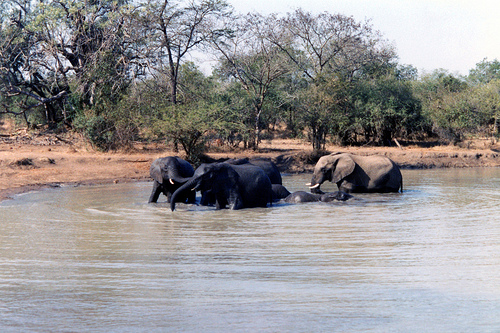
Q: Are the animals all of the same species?
A: Yes, all the animals are elephants.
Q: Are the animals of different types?
A: No, all the animals are elephants.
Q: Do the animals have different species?
A: No, all the animals are elephants.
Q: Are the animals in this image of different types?
A: No, all the animals are elephants.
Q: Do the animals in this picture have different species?
A: No, all the animals are elephants.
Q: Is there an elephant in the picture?
A: Yes, there is an elephant.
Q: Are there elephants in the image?
A: Yes, there is an elephant.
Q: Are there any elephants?
A: Yes, there is an elephant.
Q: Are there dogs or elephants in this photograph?
A: Yes, there is an elephant.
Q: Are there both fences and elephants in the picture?
A: No, there is an elephant but no fences.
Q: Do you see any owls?
A: No, there are no owls.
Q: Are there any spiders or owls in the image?
A: No, there are no owls or spiders.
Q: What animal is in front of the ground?
A: The animal is an elephant.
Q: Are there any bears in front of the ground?
A: No, there is an elephant in front of the ground.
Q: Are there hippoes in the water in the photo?
A: No, there is an elephant in the water.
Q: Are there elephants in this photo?
A: Yes, there is an elephant.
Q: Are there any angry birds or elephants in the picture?
A: Yes, there is an elephant.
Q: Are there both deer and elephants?
A: No, there is an elephant but no deer.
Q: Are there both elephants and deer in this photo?
A: No, there is an elephant but no deer.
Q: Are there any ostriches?
A: No, there are no ostriches.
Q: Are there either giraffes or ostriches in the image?
A: No, there are no ostriches or giraffes.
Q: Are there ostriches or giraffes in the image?
A: No, there are no ostriches or giraffes.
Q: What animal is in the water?
A: The animal is an elephant.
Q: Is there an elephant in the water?
A: Yes, there is an elephant in the water.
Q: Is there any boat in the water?
A: No, there is an elephant in the water.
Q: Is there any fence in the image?
A: No, there are no fences.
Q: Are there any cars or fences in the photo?
A: No, there are no fences or cars.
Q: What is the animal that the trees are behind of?
A: The animal is an elephant.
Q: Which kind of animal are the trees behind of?
A: The trees are behind the elephant.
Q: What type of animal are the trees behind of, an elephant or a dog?
A: The trees are behind an elephant.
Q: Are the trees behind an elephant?
A: Yes, the trees are behind an elephant.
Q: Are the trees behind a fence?
A: No, the trees are behind an elephant.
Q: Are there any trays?
A: No, there are no trays.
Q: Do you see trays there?
A: No, there are no trays.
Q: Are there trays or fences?
A: No, there are no trays or fences.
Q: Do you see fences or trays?
A: No, there are no trays or fences.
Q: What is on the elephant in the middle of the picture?
A: The trunk is on the elephant.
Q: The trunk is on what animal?
A: The trunk is on the elephant.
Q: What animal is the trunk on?
A: The trunk is on the elephant.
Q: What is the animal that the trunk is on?
A: The animal is an elephant.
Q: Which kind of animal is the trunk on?
A: The trunk is on the elephant.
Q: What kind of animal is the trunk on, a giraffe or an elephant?
A: The trunk is on an elephant.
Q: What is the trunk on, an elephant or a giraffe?
A: The trunk is on an elephant.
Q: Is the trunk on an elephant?
A: Yes, the trunk is on an elephant.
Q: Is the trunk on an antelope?
A: No, the trunk is on an elephant.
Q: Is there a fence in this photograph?
A: No, there are no fences.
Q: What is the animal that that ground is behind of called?
A: The animal is an elephant.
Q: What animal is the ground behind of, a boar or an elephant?
A: The ground is behind an elephant.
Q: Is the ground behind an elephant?
A: Yes, the ground is behind an elephant.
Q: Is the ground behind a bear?
A: No, the ground is behind an elephant.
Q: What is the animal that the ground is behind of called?
A: The animal is an elephant.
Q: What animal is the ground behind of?
A: The ground is behind the elephant.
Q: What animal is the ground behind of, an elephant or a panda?
A: The ground is behind an elephant.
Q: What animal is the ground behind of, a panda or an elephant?
A: The ground is behind an elephant.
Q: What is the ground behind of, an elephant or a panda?
A: The ground is behind an elephant.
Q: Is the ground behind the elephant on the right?
A: Yes, the ground is behind the elephant.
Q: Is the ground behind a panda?
A: No, the ground is behind the elephant.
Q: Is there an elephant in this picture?
A: Yes, there is an elephant.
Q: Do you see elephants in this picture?
A: Yes, there is an elephant.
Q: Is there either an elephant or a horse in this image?
A: Yes, there is an elephant.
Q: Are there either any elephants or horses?
A: Yes, there is an elephant.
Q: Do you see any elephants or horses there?
A: Yes, there is an elephant.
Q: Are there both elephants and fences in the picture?
A: No, there is an elephant but no fences.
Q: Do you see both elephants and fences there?
A: No, there is an elephant but no fences.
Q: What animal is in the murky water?
A: The elephant is in the water.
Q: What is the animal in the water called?
A: The animal is an elephant.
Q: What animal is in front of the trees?
A: The elephant is in front of the trees.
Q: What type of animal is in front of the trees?
A: The animal is an elephant.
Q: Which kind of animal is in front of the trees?
A: The animal is an elephant.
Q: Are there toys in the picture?
A: No, there are no toys.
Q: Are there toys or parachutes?
A: No, there are no toys or parachutes.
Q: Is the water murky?
A: Yes, the water is murky.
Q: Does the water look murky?
A: Yes, the water is murky.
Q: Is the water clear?
A: No, the water is murky.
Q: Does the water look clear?
A: No, the water is murky.